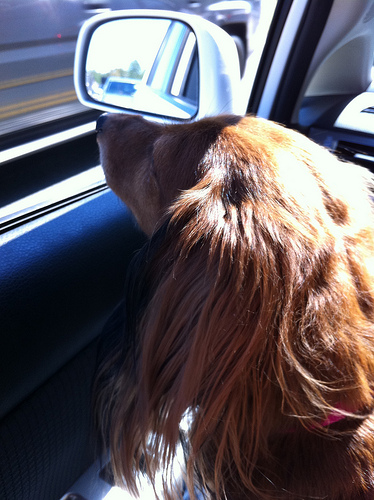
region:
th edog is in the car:
[115, 147, 373, 496]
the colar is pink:
[258, 396, 352, 445]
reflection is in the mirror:
[91, 39, 176, 108]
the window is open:
[20, 24, 257, 197]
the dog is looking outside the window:
[86, 108, 368, 392]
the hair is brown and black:
[96, 166, 245, 448]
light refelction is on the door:
[119, 445, 184, 498]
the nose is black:
[92, 108, 113, 142]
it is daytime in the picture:
[0, 5, 370, 497]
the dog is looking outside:
[85, 107, 234, 233]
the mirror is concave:
[94, 24, 193, 113]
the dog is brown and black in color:
[105, 210, 241, 397]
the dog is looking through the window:
[95, 107, 294, 244]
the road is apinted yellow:
[7, 94, 83, 107]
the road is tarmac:
[15, 56, 67, 66]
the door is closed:
[22, 134, 118, 280]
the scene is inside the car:
[23, 8, 353, 368]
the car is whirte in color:
[209, 34, 255, 112]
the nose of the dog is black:
[89, 108, 111, 130]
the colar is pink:
[285, 396, 373, 423]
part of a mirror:
[136, 37, 182, 93]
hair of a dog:
[240, 415, 288, 482]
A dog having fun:
[90, 105, 368, 314]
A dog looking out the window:
[50, 96, 337, 294]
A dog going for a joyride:
[92, 92, 319, 260]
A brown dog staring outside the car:
[76, 102, 290, 302]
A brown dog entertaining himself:
[89, 106, 329, 288]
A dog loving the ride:
[98, 106, 330, 274]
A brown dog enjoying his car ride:
[88, 109, 346, 289]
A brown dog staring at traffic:
[96, 109, 350, 307]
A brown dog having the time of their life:
[97, 111, 336, 308]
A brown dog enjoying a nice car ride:
[90, 107, 344, 294]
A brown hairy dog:
[87, 120, 370, 364]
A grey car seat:
[36, 388, 85, 469]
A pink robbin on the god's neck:
[296, 400, 347, 425]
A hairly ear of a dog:
[129, 315, 241, 391]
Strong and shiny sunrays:
[102, 451, 193, 499]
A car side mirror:
[69, 6, 223, 104]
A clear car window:
[18, 27, 62, 172]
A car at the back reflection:
[102, 75, 131, 106]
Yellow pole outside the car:
[8, 55, 39, 122]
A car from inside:
[38, 210, 370, 483]